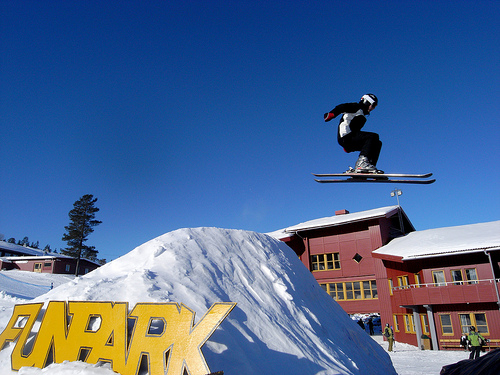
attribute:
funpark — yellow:
[29, 291, 255, 366]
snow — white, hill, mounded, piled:
[137, 238, 330, 365]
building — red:
[258, 200, 496, 343]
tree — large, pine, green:
[68, 195, 95, 269]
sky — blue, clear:
[93, 4, 245, 119]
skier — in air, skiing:
[325, 66, 407, 190]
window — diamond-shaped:
[344, 250, 363, 264]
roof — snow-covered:
[291, 203, 499, 256]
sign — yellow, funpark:
[31, 285, 207, 373]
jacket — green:
[465, 329, 484, 356]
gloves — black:
[323, 109, 340, 124]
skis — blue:
[328, 160, 436, 189]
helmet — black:
[359, 91, 393, 100]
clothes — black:
[335, 96, 374, 170]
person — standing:
[371, 321, 405, 361]